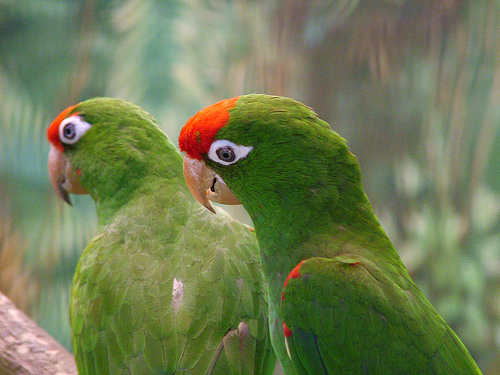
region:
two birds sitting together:
[20, 84, 484, 374]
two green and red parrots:
[38, 96, 480, 369]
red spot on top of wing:
[281, 258, 316, 349]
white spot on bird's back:
[173, 276, 189, 313]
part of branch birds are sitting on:
[2, 288, 80, 373]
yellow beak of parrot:
[182, 158, 242, 216]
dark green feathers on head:
[213, 103, 375, 249]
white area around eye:
[205, 138, 258, 166]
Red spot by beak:
[72, 160, 85, 180]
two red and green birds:
[27, 88, 497, 369]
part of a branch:
[9, 313, 44, 364]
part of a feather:
[200, 287, 235, 347]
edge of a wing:
[310, 260, 367, 332]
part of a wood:
[29, 338, 57, 360]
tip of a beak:
[193, 193, 218, 220]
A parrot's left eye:
[216, 147, 235, 164]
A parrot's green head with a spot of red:
[171, 88, 361, 240]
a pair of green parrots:
[37, 84, 478, 374]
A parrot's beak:
[179, 154, 236, 213]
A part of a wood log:
[1, 287, 84, 374]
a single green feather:
[188, 289, 213, 345]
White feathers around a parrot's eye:
[203, 135, 258, 166]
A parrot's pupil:
[221, 150, 231, 160]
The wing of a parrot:
[271, 247, 446, 374]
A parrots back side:
[81, 198, 264, 373]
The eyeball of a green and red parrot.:
[214, 147, 237, 162]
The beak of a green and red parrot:
[180, 155, 245, 215]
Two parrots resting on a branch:
[31, 96, 485, 373]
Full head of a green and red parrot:
[173, 105, 370, 216]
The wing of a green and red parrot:
[275, 253, 418, 373]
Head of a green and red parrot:
[42, 110, 176, 207]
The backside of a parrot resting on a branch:
[65, 218, 255, 373]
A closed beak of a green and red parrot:
[45, 146, 96, 208]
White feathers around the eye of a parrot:
[57, 114, 89, 145]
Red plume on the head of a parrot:
[172, 95, 236, 158]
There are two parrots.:
[26, 89, 498, 372]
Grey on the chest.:
[149, 268, 203, 328]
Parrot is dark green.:
[223, 103, 440, 373]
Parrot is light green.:
[49, 100, 261, 374]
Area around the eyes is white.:
[195, 134, 261, 172]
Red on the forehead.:
[167, 100, 232, 157]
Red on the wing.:
[273, 258, 324, 354]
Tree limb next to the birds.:
[1, 287, 61, 372]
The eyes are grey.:
[46, 117, 248, 167]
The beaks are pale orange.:
[31, 148, 241, 222]